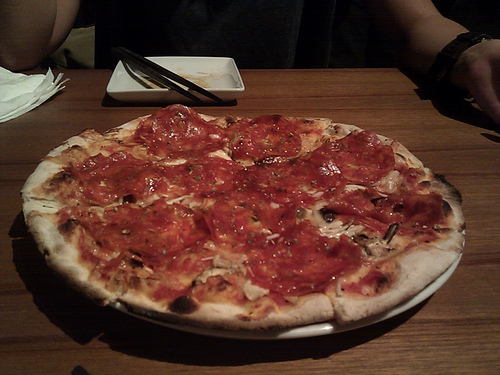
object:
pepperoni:
[133, 106, 220, 158]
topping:
[203, 207, 250, 237]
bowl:
[110, 53, 249, 105]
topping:
[248, 166, 306, 213]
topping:
[148, 261, 171, 282]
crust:
[323, 238, 472, 320]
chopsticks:
[108, 40, 228, 106]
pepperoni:
[240, 117, 300, 157]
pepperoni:
[336, 145, 398, 185]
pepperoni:
[328, 127, 381, 151]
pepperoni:
[121, 199, 214, 260]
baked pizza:
[43, 104, 467, 328]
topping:
[264, 185, 329, 225]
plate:
[108, 224, 465, 340]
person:
[1, 0, 498, 121]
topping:
[273, 182, 326, 203]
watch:
[414, 31, 483, 98]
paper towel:
[0, 59, 68, 122]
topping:
[200, 220, 229, 254]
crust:
[145, 288, 366, 330]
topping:
[285, 253, 333, 288]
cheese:
[96, 120, 138, 151]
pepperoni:
[248, 222, 359, 291]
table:
[2, 68, 495, 373]